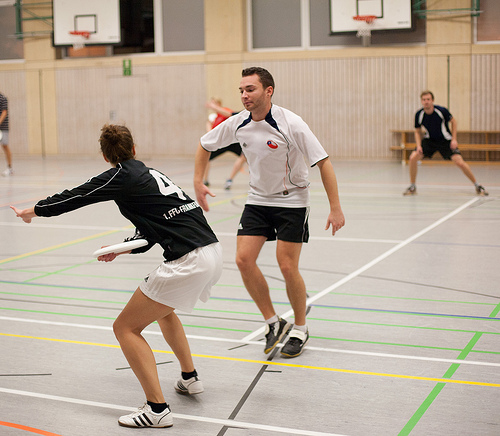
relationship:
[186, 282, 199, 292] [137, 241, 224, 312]
white colored shorts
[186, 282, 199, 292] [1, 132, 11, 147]
white colored shorts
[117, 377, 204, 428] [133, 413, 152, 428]
shoes have stripes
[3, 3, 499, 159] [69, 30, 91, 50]
wall has hoop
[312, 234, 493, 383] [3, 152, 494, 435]
lines on court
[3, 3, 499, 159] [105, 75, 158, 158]
wall has door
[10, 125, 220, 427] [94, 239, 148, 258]
person playing frisbee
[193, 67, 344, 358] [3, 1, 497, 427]
man in gym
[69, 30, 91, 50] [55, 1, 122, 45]
hoop has backboard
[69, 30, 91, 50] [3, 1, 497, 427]
hoop in a gym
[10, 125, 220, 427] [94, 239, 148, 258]
woman throwing frisbee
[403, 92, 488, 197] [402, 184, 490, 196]
man has shoes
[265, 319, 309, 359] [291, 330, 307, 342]
shoes have stripes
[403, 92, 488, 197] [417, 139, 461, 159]
man has shorts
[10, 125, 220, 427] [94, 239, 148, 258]
man has frisbee